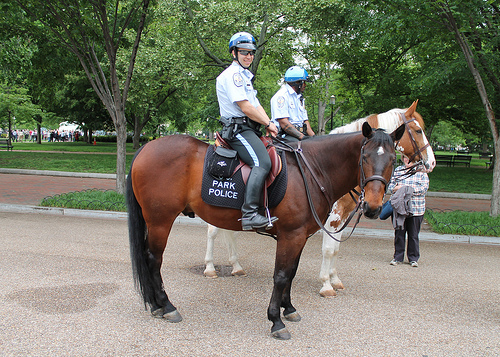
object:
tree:
[6, 2, 160, 194]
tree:
[124, 0, 296, 139]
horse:
[124, 122, 406, 341]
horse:
[201, 99, 438, 299]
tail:
[122, 173, 148, 305]